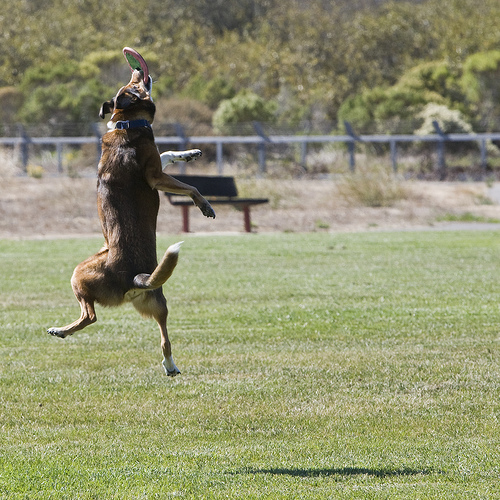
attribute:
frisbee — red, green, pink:
[124, 47, 152, 82]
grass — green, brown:
[1, 241, 499, 499]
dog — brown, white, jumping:
[47, 68, 217, 379]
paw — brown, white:
[161, 150, 202, 164]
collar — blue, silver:
[107, 119, 154, 129]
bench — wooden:
[165, 175, 270, 234]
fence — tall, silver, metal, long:
[1, 128, 498, 192]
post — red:
[183, 205, 190, 235]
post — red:
[245, 208, 252, 233]